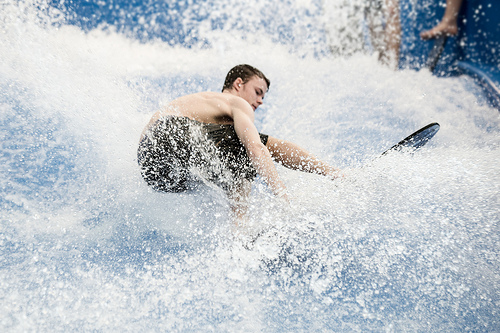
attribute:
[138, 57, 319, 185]
boy — surfing, playing, young, topless, surfboarding, training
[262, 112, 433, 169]
surfboard — blue, black, water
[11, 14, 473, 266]
waves — white, crashing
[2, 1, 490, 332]
water — blue, splashing, white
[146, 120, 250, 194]
shorts — black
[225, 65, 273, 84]
hair — brown